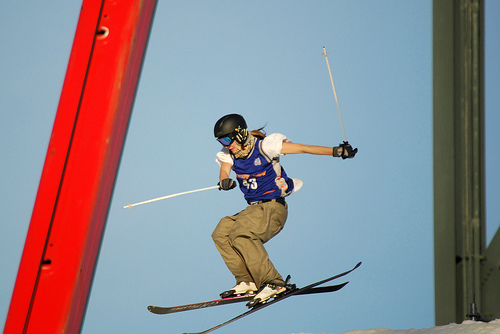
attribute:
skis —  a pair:
[154, 230, 391, 325]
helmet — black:
[197, 97, 259, 135]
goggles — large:
[221, 135, 241, 147]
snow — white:
[373, 309, 495, 331]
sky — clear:
[2, 3, 449, 332]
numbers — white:
[242, 175, 259, 190]